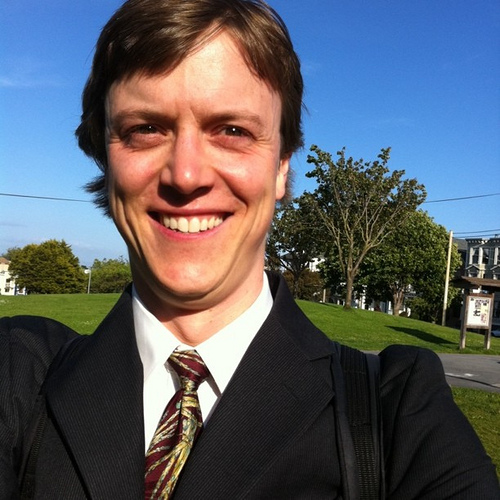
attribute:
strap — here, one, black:
[321, 339, 394, 499]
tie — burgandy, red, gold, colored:
[142, 340, 206, 498]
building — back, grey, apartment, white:
[0, 256, 28, 297]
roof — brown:
[0, 253, 12, 264]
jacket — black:
[0, 269, 500, 498]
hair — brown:
[117, 8, 175, 62]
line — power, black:
[426, 185, 497, 217]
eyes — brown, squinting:
[121, 114, 257, 149]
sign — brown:
[456, 291, 497, 352]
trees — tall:
[267, 145, 447, 324]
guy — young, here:
[2, 2, 499, 498]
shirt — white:
[128, 271, 277, 471]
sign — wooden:
[455, 288, 495, 355]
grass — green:
[3, 293, 107, 315]